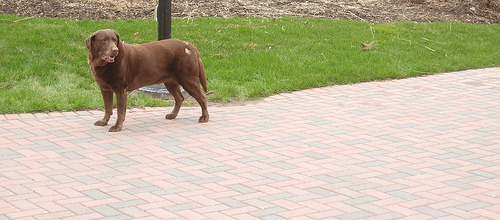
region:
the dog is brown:
[66, 31, 245, 130]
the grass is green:
[227, 59, 303, 88]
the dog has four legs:
[88, 66, 231, 126]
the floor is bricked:
[208, 122, 330, 187]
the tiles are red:
[149, 147, 334, 186]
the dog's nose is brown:
[86, 33, 128, 69]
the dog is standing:
[59, 12, 251, 117]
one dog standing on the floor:
[70, 24, 250, 141]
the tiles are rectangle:
[214, 148, 316, 215]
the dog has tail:
[188, 43, 225, 123]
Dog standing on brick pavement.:
[85, 25, 208, 131]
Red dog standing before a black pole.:
[87, 1, 303, 214]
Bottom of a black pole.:
[142, 1, 192, 106]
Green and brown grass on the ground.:
[207, 18, 498, 70]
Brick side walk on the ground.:
[1, 67, 498, 219]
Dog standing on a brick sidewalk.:
[1, 27, 498, 217]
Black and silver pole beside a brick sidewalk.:
[100, 0, 498, 219]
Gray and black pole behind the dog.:
[85, 0, 209, 135]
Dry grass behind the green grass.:
[182, 1, 498, 18]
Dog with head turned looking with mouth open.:
[85, 30, 210, 218]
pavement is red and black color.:
[81, 138, 348, 219]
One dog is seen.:
[70, 30, 205, 140]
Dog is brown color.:
[70, 25, 212, 135]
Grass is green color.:
[225, 35, 340, 75]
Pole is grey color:
[135, 0, 182, 80]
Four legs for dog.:
[95, 86, 227, 122]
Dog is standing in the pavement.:
[90, 35, 225, 145]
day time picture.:
[15, 25, 480, 195]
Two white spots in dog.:
[178, 41, 194, 58]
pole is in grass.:
[133, 13, 218, 95]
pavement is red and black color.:
[183, 133, 420, 209]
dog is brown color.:
[80, 25, 215, 125]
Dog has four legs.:
[91, 85, 241, 135]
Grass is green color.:
[10, 30, 60, 97]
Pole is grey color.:
[136, 7, 186, 52]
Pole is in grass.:
[145, 0, 227, 97]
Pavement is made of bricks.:
[75, 140, 295, 193]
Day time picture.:
[8, 22, 498, 211]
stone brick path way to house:
[226, 133, 442, 199]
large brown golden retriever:
[65, 29, 222, 119]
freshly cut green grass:
[252, 32, 386, 68]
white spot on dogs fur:
[176, 39, 210, 66]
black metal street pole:
[142, 10, 195, 40]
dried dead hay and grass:
[257, 0, 428, 15]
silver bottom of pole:
[147, 88, 174, 102]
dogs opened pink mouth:
[99, 53, 116, 62]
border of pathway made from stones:
[8, 109, 88, 119]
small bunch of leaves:
[360, 36, 388, 63]